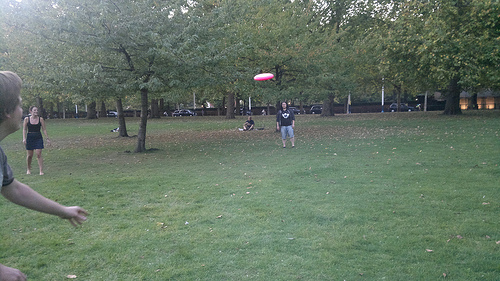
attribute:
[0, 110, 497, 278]
grass — short, brown, green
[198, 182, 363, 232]
grass — short, green, brown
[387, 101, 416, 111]
car — black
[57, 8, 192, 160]
tree — leafy, green, tall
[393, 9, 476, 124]
tree — leafy, green, tall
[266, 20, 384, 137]
tree — leafy, green, tall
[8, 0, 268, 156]
tree — green, tall, leafy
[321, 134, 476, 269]
grass — green, brown, short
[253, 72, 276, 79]
frisbee — red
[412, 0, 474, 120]
tree — tall, leafy, green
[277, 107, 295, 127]
shirt — black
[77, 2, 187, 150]
leafy tree — green, tall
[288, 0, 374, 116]
leafy tree — tall, green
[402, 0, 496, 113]
leafy tree — tall, green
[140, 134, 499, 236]
grass — short, green, brown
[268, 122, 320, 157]
jeans — blue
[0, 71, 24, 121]
hair — brown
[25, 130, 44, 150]
skirt — blue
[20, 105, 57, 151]
shirt — black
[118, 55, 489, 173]
wall — brick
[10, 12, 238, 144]
tree — leafy, tall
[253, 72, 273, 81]
frisbee — red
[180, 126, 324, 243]
grass — green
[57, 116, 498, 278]
grass — brown, green, short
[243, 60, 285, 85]
frisbee — pink, plastic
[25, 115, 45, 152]
dress — black